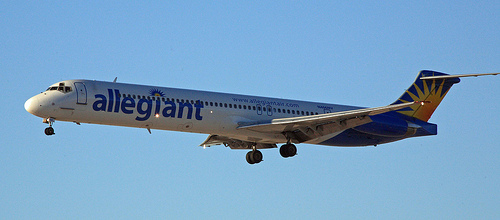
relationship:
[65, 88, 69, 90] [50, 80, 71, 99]
window of cockpit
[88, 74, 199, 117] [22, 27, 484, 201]
words of plane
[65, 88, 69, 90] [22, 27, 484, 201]
window of plane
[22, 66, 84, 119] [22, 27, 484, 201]
nose of plane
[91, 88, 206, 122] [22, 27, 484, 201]
print of plane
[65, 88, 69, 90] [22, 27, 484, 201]
window on plane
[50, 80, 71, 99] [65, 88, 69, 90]
cockpit has window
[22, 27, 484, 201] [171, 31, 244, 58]
plane in sky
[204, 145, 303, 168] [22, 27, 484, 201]
wheel of plane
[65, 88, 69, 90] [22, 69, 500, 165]
window on airplane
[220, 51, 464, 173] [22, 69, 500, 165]
wing of airplane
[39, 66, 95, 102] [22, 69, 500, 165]
windshield of airplane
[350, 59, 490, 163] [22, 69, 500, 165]
tail of airplane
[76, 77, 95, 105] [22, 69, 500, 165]
door of airplane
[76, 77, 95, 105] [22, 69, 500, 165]
door on airplane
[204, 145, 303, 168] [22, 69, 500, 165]
wheel on airplane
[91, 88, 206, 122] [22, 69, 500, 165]
print on airplane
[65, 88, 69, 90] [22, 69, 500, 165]
window of airplane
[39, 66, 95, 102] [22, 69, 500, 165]
windshield on airplane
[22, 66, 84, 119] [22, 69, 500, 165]
nose of airplane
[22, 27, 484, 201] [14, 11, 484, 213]
airplane on sky